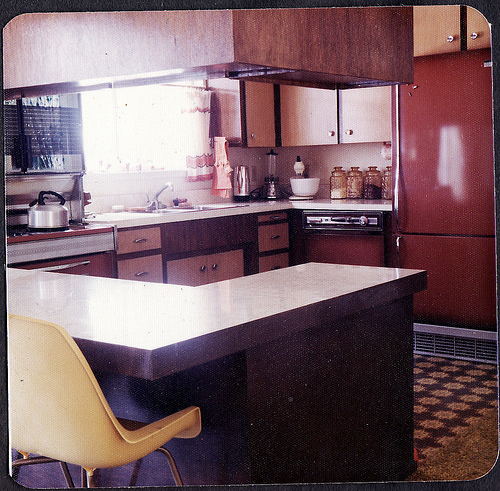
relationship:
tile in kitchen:
[416, 370, 443, 391] [3, 14, 490, 476]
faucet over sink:
[141, 181, 176, 210] [113, 189, 251, 216]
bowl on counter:
[288, 176, 323, 196] [0, 196, 430, 379]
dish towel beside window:
[213, 137, 231, 197] [75, 78, 210, 167]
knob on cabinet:
[327, 131, 334, 138] [278, 82, 338, 147]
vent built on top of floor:
[411, 322, 498, 365] [416, 346, 484, 482]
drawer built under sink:
[118, 225, 162, 255] [107, 200, 248, 217]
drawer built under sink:
[118, 254, 163, 282] [107, 200, 248, 217]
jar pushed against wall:
[321, 163, 349, 207] [302, 141, 382, 166]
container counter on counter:
[318, 163, 391, 204] [117, 197, 281, 225]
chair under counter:
[1, 307, 33, 345] [137, 308, 318, 472]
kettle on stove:
[26, 165, 73, 252] [23, 172, 164, 275]